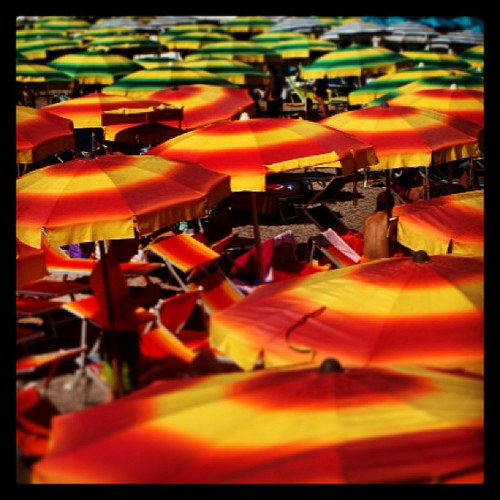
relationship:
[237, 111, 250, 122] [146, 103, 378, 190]
tip of umbrella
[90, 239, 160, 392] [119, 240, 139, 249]
man wearing glasses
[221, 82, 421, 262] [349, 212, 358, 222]
sand has footprints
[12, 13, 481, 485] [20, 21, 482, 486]
umbrella on beach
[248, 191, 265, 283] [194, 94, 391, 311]
pole on umbrella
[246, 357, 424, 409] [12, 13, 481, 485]
top of umbrella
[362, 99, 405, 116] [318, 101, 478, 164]
top of umbrella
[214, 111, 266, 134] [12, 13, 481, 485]
top of umbrella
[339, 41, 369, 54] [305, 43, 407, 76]
top of umbrella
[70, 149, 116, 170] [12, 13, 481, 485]
top of umbrella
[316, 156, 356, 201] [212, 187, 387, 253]
chair on sand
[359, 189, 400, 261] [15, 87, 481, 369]
man by umbrellas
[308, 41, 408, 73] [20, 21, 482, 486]
umbrella on beach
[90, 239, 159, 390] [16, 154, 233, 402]
man under umbrella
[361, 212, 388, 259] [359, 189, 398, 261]
back of man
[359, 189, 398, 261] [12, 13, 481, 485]
man under umbrella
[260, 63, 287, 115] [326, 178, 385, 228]
person standing sand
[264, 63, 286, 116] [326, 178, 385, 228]
person standing sand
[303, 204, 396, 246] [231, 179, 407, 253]
seat in sand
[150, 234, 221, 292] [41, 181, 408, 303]
seat in sand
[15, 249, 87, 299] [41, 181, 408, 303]
seat in sand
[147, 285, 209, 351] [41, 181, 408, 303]
seat in sand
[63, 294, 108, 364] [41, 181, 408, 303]
seat in sand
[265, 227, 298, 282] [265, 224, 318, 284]
towel on chair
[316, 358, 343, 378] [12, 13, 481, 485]
tip of umbrella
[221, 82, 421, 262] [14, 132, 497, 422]
sand on ground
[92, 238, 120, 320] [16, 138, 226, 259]
unbrella pole of umbrella